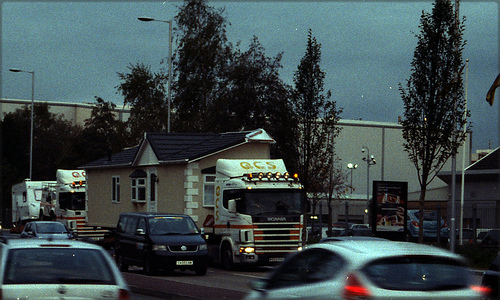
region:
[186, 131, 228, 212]
Big trailer on the side of a truck.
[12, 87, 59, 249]
Big trailer on the side of a truck.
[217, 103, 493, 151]
Big trailer on the side of a truck.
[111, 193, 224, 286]
Car parked beside building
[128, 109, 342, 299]
Tractor trailer pulling a building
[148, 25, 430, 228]
Trees beside the street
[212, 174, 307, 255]
Windshield on front of truck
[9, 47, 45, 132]
Light pole beside the street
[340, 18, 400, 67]
Sky is full of clouds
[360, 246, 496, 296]
Back window on the car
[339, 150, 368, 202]
The street light is turned on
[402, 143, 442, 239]
Small trunk on the tree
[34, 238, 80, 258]
Light on back of car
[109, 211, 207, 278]
black minivan on the road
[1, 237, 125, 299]
white station wagon on road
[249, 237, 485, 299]
white car on road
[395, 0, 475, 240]
tree behind car on road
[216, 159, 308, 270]
white truck on the road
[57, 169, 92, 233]
white truck on the road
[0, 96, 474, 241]
large tan warehouse behind car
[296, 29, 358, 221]
tree is next to tree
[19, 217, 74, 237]
gray car on road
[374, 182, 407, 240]
black sign on sidewalk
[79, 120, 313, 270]
A truck in the background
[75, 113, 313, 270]
Truck is carrying a small house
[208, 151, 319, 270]
A front view of a truck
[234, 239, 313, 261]
Truck headlights are on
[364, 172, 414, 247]
A poster sign in the background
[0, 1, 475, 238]
Tall trees in the background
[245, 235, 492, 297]
The back view of a car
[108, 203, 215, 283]
A dark colored van in the background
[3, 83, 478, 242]
A building in the background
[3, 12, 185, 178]
Street poles in the background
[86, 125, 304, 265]
A truck is pulling half of a house.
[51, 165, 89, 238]
A truck has a spoiler on top.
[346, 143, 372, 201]
Street lights vare on two posts.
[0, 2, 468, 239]
Green trees are by the side of the road. .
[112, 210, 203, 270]
The van is a charcoal color.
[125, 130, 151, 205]
A bay window is under the "A" roof shape.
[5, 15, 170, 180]
Two lights are over the street.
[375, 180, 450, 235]
A car is by a sign.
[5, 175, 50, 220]
A trailer is behind a truck.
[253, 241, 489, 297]
A moving car has taillights on.